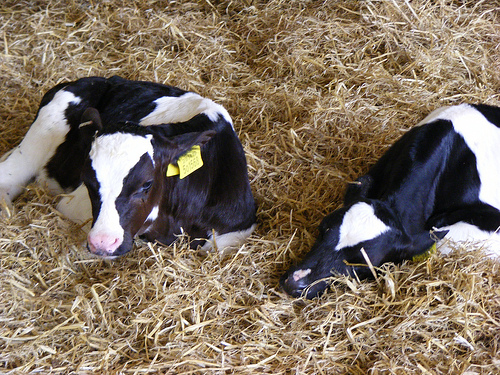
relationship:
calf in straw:
[4, 68, 260, 279] [5, 274, 185, 346]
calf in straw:
[277, 81, 497, 307] [5, 274, 185, 346]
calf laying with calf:
[4, 68, 260, 279] [277, 81, 497, 307]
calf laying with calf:
[277, 81, 497, 307] [4, 68, 260, 279]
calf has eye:
[0, 74, 256, 260] [136, 177, 153, 193]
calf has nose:
[0, 74, 256, 260] [89, 230, 119, 250]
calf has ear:
[0, 74, 256, 260] [153, 131, 210, 165]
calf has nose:
[282, 102, 500, 300] [278, 271, 323, 302]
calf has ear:
[282, 102, 500, 300] [405, 216, 446, 266]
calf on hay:
[0, 74, 256, 260] [3, 1, 499, 372]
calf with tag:
[4, 68, 260, 279] [168, 146, 208, 183]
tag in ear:
[168, 146, 208, 183] [151, 118, 231, 168]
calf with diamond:
[277, 81, 497, 307] [335, 204, 392, 250]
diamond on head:
[335, 204, 392, 250] [277, 175, 461, 315]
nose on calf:
[86, 231, 121, 252] [0, 74, 256, 260]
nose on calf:
[279, 261, 321, 294] [277, 81, 497, 307]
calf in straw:
[282, 102, 500, 300] [1, 0, 497, 373]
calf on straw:
[0, 74, 256, 260] [1, 0, 497, 373]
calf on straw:
[282, 102, 500, 300] [1, 0, 497, 373]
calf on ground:
[282, 102, 500, 300] [0, 0, 500, 375]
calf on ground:
[0, 74, 256, 260] [0, 0, 500, 375]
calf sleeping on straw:
[282, 102, 500, 300] [1, 0, 497, 373]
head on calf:
[61, 98, 221, 257] [0, 74, 256, 260]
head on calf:
[278, 170, 448, 297] [282, 102, 500, 300]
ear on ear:
[160, 123, 224, 177] [383, 224, 448, 255]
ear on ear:
[65, 111, 103, 149] [383, 224, 448, 255]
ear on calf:
[336, 173, 378, 207] [282, 102, 500, 300]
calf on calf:
[0, 74, 256, 260] [282, 102, 500, 300]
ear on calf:
[160, 121, 215, 177] [0, 74, 256, 260]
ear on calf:
[65, 111, 103, 149] [0, 74, 256, 260]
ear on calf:
[387, 227, 447, 258] [282, 102, 500, 300]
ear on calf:
[336, 169, 373, 207] [282, 102, 500, 300]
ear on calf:
[63, 100, 103, 149] [0, 74, 256, 260]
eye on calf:
[132, 177, 154, 196] [0, 74, 256, 260]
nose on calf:
[279, 261, 321, 294] [282, 102, 500, 300]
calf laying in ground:
[0, 74, 256, 260] [0, 0, 500, 375]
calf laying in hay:
[282, 102, 500, 300] [292, 305, 412, 360]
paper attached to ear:
[174, 150, 204, 176] [154, 139, 196, 160]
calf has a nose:
[282, 102, 500, 300] [279, 265, 309, 297]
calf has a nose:
[0, 74, 256, 260] [87, 233, 124, 257]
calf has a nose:
[282, 102, 500, 300] [284, 269, 306, 301]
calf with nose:
[0, 74, 256, 260] [64, 207, 182, 295]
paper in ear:
[165, 142, 204, 179] [147, 26, 243, 197]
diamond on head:
[335, 204, 392, 250] [255, 110, 415, 341]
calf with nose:
[282, 102, 500, 300] [286, 174, 399, 334]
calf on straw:
[0, 74, 256, 260] [37, 227, 473, 367]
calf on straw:
[0, 74, 256, 260] [29, 210, 452, 365]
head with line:
[61, 98, 221, 257] [134, 90, 162, 196]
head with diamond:
[278, 170, 448, 297] [317, 179, 408, 269]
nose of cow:
[69, 177, 151, 295] [29, 68, 302, 290]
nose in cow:
[279, 261, 321, 294] [291, 107, 446, 323]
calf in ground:
[282, 102, 500, 300] [16, 18, 469, 368]